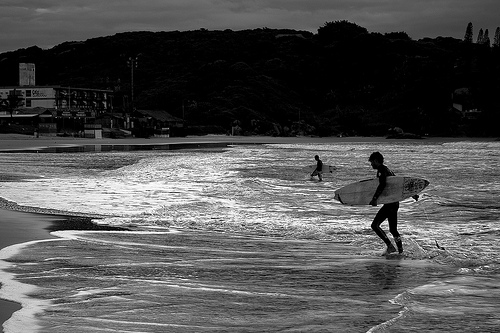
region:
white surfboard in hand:
[321, 177, 437, 203]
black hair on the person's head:
[366, 151, 383, 159]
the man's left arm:
[369, 169, 385, 212]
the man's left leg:
[392, 203, 409, 259]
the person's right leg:
[369, 209, 393, 255]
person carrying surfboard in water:
[304, 154, 342, 181]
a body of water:
[118, 176, 283, 250]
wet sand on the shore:
[0, 208, 37, 245]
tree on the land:
[0, 89, 30, 129]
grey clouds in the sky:
[91, 0, 284, 29]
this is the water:
[180, 161, 280, 261]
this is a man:
[368, 152, 404, 262]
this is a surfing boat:
[339, 176, 422, 201]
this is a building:
[16, 82, 107, 109]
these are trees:
[145, 42, 360, 72]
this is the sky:
[4, 34, 54, 43]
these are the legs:
[373, 215, 403, 257]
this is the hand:
[372, 176, 384, 207]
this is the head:
[366, 153, 383, 168]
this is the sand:
[4, 220, 29, 235]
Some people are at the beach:
[20, 55, 492, 330]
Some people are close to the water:
[36, 71, 481, 321]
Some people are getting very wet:
[33, 73, 488, 330]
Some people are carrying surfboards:
[25, 40, 482, 311]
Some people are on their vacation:
[40, 102, 476, 320]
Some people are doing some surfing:
[18, 96, 486, 324]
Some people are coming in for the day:
[45, 122, 462, 315]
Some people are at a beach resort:
[28, 100, 474, 316]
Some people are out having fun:
[50, 105, 468, 325]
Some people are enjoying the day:
[28, 113, 470, 325]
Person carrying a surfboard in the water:
[346, 137, 410, 267]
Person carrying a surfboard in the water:
[301, 133, 328, 186]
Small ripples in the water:
[121, 202, 166, 236]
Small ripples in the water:
[203, 211, 248, 241]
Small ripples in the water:
[259, 209, 291, 238]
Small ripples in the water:
[292, 206, 330, 256]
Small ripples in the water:
[339, 213, 372, 244]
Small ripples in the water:
[410, 228, 442, 265]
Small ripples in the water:
[435, 229, 477, 267]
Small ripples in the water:
[357, 309, 409, 328]